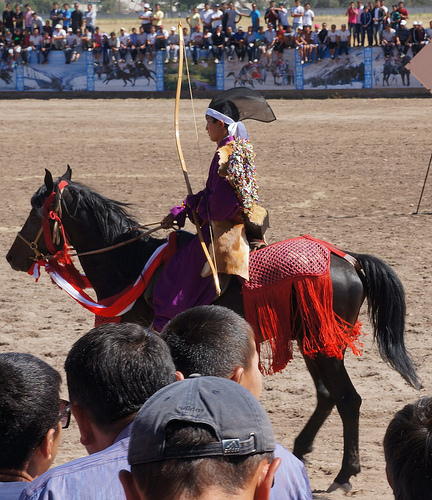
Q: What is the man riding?
A: A horse.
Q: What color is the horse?
A: Dark brown.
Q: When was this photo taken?
A: In the daytime.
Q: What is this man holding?
A: A bow.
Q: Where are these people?
A: A horsing event.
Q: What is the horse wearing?
A: Red shawl.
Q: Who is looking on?
A: A crowd.